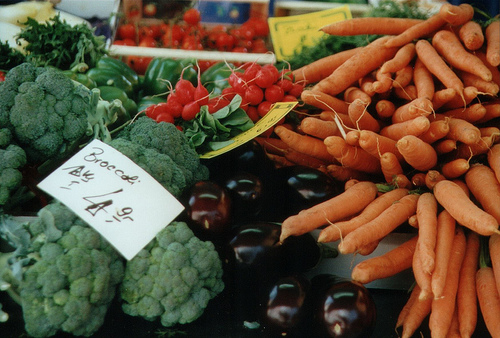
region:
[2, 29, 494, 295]
Fresh produce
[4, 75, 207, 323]
fresh broccoli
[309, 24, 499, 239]
Fresh carrots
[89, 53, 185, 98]
fresh green peppers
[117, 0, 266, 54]
fresh strawberries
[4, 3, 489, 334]
Fresh vegetables and fruits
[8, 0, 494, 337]
Raw vegetables and fruits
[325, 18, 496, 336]
Orange carrots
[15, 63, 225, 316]
green bunches of broccoli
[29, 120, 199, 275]
A piece of paper designating the price of the broccoli.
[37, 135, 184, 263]
White sign on top of broccoli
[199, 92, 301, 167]
Yellow paper in front of radish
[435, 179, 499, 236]
Orange carrot next to orange carrot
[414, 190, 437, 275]
Orange carrot next to orange carrot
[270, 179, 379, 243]
Orange carrot next to orange carrot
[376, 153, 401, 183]
Orange carrot next to orange carrot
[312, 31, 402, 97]
Orange carrot next to orange carrot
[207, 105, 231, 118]
Green leaf by radish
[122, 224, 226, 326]
Big green broccoli next to big green broccoli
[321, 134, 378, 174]
Orange carrot next to orange carrot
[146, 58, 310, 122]
Red radishes clumped together.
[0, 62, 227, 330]
Broccoli sitting under a label.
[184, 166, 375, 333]
Purple plums laying next to broccoli.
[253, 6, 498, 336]
A bunch of carrots laying randomly.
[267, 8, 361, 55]
A blurry yellow label by carrots.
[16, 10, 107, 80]
Some kale hiding behind peppers.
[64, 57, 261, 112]
Green peppers laying in the background.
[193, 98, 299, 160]
A yellow label sideways that you can't read.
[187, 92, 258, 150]
Some lettuce under some radishes.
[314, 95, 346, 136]
A white root of a carrot.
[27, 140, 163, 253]
this is a a price tagr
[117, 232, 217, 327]
this is a cauliflower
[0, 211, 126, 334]
this is a cauliflower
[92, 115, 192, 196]
this is a cauliflower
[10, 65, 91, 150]
this is a cauliflower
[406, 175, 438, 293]
this is a carrot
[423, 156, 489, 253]
this is a carrot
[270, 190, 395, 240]
this is a carrot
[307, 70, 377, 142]
this is a carrot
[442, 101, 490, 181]
this is a carrot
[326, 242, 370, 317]
part of a carrot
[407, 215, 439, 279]
part of a carrot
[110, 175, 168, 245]
part of a paper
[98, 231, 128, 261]
edge of a paper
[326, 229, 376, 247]
part of a carrot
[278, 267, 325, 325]
edge of a palm